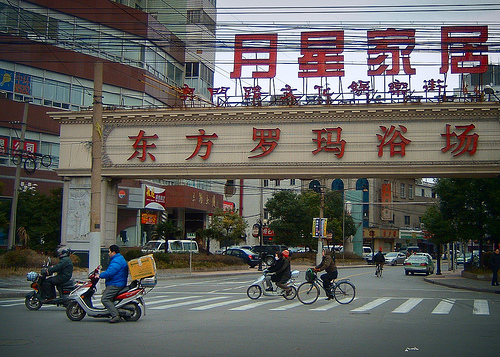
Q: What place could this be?
A: It is a street.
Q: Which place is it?
A: It is a street.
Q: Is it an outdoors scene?
A: Yes, it is outdoors.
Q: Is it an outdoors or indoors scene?
A: It is outdoors.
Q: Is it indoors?
A: No, it is outdoors.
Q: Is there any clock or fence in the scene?
A: No, there are no fences or clocks.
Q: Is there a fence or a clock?
A: No, there are no fences or clocks.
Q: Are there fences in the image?
A: No, there are no fences.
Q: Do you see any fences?
A: No, there are no fences.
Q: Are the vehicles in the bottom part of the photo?
A: Yes, the vehicles are in the bottom of the image.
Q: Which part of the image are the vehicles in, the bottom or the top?
A: The vehicles are in the bottom of the image.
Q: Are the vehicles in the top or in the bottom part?
A: The vehicles are in the bottom of the image.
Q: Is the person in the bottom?
A: Yes, the person is in the bottom of the image.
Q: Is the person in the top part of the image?
A: No, the person is in the bottom of the image.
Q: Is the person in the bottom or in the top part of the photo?
A: The person is in the bottom of the image.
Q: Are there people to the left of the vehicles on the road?
A: Yes, there is a person to the left of the vehicles.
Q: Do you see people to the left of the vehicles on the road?
A: Yes, there is a person to the left of the vehicles.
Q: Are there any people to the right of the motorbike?
A: Yes, there is a person to the right of the motorbike.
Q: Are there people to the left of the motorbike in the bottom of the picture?
A: No, the person is to the right of the motorbike.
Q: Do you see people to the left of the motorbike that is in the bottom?
A: No, the person is to the right of the motorbike.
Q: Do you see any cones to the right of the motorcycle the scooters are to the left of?
A: No, there is a person to the right of the motorbike.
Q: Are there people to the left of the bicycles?
A: Yes, there is a person to the left of the bicycles.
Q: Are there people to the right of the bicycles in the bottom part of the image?
A: No, the person is to the left of the bicycles.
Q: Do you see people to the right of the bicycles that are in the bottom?
A: No, the person is to the left of the bicycles.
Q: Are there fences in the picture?
A: No, there are no fences.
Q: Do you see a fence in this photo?
A: No, there are no fences.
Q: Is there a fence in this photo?
A: No, there are no fences.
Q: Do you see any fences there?
A: No, there are no fences.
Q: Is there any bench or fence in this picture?
A: No, there are no fences or benches.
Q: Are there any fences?
A: No, there are no fences.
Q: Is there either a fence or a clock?
A: No, there are no fences or clocks.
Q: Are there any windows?
A: Yes, there are windows.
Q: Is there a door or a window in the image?
A: Yes, there are windows.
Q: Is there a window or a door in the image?
A: Yes, there are windows.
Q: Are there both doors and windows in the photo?
A: No, there are windows but no doors.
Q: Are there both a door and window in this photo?
A: No, there are windows but no doors.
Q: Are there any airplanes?
A: No, there are no airplanes.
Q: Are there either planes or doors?
A: No, there are no planes or doors.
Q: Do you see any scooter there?
A: Yes, there are scooters.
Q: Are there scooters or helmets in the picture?
A: Yes, there are scooters.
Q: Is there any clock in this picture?
A: No, there are no clocks.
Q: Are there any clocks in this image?
A: No, there are no clocks.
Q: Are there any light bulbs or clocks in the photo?
A: No, there are no clocks or light bulbs.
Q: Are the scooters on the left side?
A: Yes, the scooters are on the left of the image.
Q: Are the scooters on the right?
A: No, the scooters are on the left of the image.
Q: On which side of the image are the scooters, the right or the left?
A: The scooters are on the left of the image.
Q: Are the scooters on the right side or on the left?
A: The scooters are on the left of the image.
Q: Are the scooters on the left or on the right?
A: The scooters are on the left of the image.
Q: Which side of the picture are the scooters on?
A: The scooters are on the left of the image.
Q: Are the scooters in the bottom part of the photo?
A: Yes, the scooters are in the bottom of the image.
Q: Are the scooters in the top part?
A: No, the scooters are in the bottom of the image.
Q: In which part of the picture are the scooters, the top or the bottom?
A: The scooters are in the bottom of the image.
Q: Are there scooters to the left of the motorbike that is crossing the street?
A: Yes, there are scooters to the left of the motorbike.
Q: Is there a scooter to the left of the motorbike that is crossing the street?
A: Yes, there are scooters to the left of the motorbike.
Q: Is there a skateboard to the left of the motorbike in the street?
A: No, there are scooters to the left of the motorcycle.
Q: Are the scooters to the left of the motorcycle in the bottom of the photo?
A: Yes, the scooters are to the left of the motorbike.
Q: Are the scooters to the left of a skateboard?
A: No, the scooters are to the left of the motorbike.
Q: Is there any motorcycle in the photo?
A: Yes, there is a motorcycle.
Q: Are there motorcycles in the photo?
A: Yes, there is a motorcycle.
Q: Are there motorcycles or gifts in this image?
A: Yes, there is a motorcycle.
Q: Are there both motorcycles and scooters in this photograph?
A: Yes, there are both a motorcycle and a scooter.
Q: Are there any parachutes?
A: No, there are no parachutes.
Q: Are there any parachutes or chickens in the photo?
A: No, there are no parachutes or chickens.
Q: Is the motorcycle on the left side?
A: Yes, the motorcycle is on the left of the image.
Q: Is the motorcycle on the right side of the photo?
A: No, the motorcycle is on the left of the image.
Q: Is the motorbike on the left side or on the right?
A: The motorbike is on the left of the image.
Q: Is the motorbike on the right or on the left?
A: The motorbike is on the left of the image.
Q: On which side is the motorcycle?
A: The motorcycle is on the left of the image.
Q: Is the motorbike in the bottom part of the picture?
A: Yes, the motorbike is in the bottom of the image.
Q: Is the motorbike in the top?
A: No, the motorbike is in the bottom of the image.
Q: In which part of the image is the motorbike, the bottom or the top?
A: The motorbike is in the bottom of the image.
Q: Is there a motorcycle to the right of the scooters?
A: Yes, there is a motorcycle to the right of the scooters.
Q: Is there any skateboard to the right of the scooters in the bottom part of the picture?
A: No, there is a motorcycle to the right of the scooters.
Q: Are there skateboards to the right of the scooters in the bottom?
A: No, there is a motorcycle to the right of the scooters.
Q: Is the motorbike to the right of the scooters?
A: Yes, the motorbike is to the right of the scooters.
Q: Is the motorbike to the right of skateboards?
A: No, the motorbike is to the right of the scooters.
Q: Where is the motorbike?
A: The motorbike is in the street.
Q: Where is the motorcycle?
A: The motorbike is in the street.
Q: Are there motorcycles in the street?
A: Yes, there is a motorcycle in the street.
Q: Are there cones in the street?
A: No, there is a motorcycle in the street.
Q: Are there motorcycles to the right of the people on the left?
A: Yes, there is a motorcycle to the right of the people.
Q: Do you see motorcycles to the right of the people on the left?
A: Yes, there is a motorcycle to the right of the people.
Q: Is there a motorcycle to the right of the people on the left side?
A: Yes, there is a motorcycle to the right of the people.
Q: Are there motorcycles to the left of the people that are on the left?
A: No, the motorcycle is to the right of the people.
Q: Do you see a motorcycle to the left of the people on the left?
A: No, the motorcycle is to the right of the people.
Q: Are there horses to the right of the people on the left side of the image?
A: No, there is a motorcycle to the right of the people.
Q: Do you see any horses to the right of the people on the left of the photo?
A: No, there is a motorcycle to the right of the people.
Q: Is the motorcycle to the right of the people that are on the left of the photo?
A: Yes, the motorcycle is to the right of the people.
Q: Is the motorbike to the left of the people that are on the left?
A: No, the motorbike is to the right of the people.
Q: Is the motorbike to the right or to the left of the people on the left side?
A: The motorbike is to the right of the people.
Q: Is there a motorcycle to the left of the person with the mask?
A: Yes, there is a motorcycle to the left of the person.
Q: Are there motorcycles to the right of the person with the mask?
A: No, the motorcycle is to the left of the person.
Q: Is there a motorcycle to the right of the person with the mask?
A: No, the motorcycle is to the left of the person.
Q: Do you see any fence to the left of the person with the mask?
A: No, there is a motorcycle to the left of the person.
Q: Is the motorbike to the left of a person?
A: Yes, the motorbike is to the left of a person.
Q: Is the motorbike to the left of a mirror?
A: No, the motorbike is to the left of a person.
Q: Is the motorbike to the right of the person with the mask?
A: No, the motorbike is to the left of the person.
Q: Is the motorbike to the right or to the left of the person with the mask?
A: The motorbike is to the left of the person.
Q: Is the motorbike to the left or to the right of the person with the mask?
A: The motorbike is to the left of the person.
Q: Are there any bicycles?
A: Yes, there are bicycles.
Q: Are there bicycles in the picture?
A: Yes, there are bicycles.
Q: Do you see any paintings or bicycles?
A: Yes, there are bicycles.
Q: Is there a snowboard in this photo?
A: No, there are no snowboards.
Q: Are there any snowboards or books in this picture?
A: No, there are no snowboards or books.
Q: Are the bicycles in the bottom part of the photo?
A: Yes, the bicycles are in the bottom of the image.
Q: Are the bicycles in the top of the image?
A: No, the bicycles are in the bottom of the image.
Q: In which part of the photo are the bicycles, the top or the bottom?
A: The bicycles are in the bottom of the image.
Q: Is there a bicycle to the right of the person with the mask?
A: Yes, there are bicycles to the right of the person.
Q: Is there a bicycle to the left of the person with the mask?
A: No, the bicycles are to the right of the person.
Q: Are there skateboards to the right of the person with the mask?
A: No, there are bicycles to the right of the person.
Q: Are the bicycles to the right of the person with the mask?
A: Yes, the bicycles are to the right of the person.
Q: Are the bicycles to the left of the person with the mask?
A: No, the bicycles are to the right of the person.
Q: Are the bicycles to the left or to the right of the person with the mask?
A: The bicycles are to the right of the person.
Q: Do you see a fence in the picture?
A: No, there are no fences.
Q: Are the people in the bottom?
A: Yes, the people are in the bottom of the image.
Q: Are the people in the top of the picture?
A: No, the people are in the bottom of the image.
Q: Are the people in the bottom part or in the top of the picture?
A: The people are in the bottom of the image.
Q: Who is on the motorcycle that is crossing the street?
A: The people are on the motorcycle.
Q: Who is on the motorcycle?
A: The people are on the motorcycle.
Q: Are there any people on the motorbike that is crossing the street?
A: Yes, there are people on the motorbike.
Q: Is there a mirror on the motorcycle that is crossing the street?
A: No, there are people on the motorcycle.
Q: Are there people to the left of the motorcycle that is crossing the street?
A: Yes, there are people to the left of the motorcycle.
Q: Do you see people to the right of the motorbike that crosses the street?
A: No, the people are to the left of the motorbike.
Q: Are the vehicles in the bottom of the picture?
A: Yes, the vehicles are in the bottom of the image.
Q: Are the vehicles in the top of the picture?
A: No, the vehicles are in the bottom of the image.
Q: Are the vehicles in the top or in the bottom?
A: The vehicles are in the bottom of the image.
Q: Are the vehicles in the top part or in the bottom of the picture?
A: The vehicles are in the bottom of the image.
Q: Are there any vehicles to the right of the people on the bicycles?
A: Yes, there are vehicles to the right of the people.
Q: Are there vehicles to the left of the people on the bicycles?
A: No, the vehicles are to the right of the people.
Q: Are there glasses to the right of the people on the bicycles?
A: No, there are vehicles to the right of the people.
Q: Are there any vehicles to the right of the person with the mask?
A: Yes, there are vehicles to the right of the person.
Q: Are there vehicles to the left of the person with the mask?
A: No, the vehicles are to the right of the person.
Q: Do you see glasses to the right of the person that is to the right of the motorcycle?
A: No, there are vehicles to the right of the person.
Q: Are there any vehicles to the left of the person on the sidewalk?
A: Yes, there are vehicles to the left of the person.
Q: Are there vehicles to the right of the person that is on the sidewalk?
A: No, the vehicles are to the left of the person.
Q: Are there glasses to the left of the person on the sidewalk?
A: No, there are vehicles to the left of the person.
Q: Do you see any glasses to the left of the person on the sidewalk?
A: No, there are vehicles to the left of the person.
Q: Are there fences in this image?
A: No, there are no fences.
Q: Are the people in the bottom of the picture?
A: Yes, the people are in the bottom of the image.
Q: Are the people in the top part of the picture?
A: No, the people are in the bottom of the image.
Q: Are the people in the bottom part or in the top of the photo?
A: The people are in the bottom of the image.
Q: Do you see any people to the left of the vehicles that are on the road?
A: Yes, there are people to the left of the vehicles.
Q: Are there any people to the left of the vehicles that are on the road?
A: Yes, there are people to the left of the vehicles.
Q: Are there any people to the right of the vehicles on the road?
A: No, the people are to the left of the vehicles.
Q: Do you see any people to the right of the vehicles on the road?
A: No, the people are to the left of the vehicles.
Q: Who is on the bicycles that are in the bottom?
A: The people are on the bicycles.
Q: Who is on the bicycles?
A: The people are on the bicycles.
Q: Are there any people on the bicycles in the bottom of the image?
A: Yes, there are people on the bicycles.